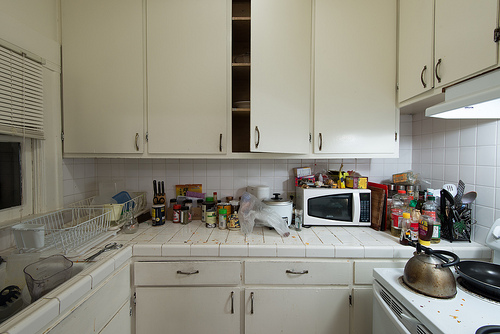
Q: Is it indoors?
A: Yes, it is indoors.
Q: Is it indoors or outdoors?
A: It is indoors.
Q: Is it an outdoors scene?
A: No, it is indoors.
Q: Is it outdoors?
A: No, it is indoors.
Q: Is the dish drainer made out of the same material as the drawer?
A: No, the dish drainer is made of plastic and the drawer is made of wood.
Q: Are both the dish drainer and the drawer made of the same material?
A: No, the dish drainer is made of plastic and the drawer is made of wood.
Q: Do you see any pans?
A: Yes, there is a pan.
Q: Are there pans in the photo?
A: Yes, there is a pan.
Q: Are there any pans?
A: Yes, there is a pan.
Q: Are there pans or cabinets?
A: Yes, there is a pan.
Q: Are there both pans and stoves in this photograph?
A: Yes, there are both a pan and a stove.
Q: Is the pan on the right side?
A: Yes, the pan is on the right of the image.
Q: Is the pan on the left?
A: No, the pan is on the right of the image.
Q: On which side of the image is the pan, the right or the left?
A: The pan is on the right of the image.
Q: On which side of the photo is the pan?
A: The pan is on the right of the image.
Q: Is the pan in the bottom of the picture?
A: Yes, the pan is in the bottom of the image.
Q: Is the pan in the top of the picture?
A: No, the pan is in the bottom of the image.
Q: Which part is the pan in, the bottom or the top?
A: The pan is in the bottom of the image.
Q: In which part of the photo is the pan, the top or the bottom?
A: The pan is in the bottom of the image.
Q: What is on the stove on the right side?
A: The pan is on the stove.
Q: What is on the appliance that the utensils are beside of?
A: The pan is on the stove.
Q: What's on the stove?
A: The pan is on the stove.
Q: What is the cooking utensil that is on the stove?
A: The cooking utensil is a pan.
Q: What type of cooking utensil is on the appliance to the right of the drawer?
A: The cooking utensil is a pan.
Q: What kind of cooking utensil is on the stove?
A: The cooking utensil is a pan.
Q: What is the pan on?
A: The pan is on the stove.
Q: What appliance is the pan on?
A: The pan is on the stove.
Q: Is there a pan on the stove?
A: Yes, there is a pan on the stove.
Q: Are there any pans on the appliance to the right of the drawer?
A: Yes, there is a pan on the stove.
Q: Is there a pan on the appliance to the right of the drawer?
A: Yes, there is a pan on the stove.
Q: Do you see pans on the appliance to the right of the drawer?
A: Yes, there is a pan on the stove.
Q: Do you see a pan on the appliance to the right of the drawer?
A: Yes, there is a pan on the stove.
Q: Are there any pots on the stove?
A: No, there is a pan on the stove.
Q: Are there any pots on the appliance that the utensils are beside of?
A: No, there is a pan on the stove.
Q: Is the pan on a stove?
A: Yes, the pan is on a stove.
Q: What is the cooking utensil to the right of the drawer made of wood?
A: The cooking utensil is a pan.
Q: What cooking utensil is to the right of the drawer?
A: The cooking utensil is a pan.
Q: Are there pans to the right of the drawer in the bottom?
A: Yes, there is a pan to the right of the drawer.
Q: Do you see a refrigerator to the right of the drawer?
A: No, there is a pan to the right of the drawer.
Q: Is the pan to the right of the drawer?
A: Yes, the pan is to the right of the drawer.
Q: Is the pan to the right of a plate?
A: No, the pan is to the right of the drawer.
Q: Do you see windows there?
A: Yes, there is a window.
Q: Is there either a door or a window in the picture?
A: Yes, there is a window.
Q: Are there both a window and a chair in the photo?
A: No, there is a window but no chairs.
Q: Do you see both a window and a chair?
A: No, there is a window but no chairs.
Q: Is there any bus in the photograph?
A: No, there are no buses.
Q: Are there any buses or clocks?
A: No, there are no buses or clocks.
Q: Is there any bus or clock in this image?
A: No, there are no buses or clocks.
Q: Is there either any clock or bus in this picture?
A: No, there are no buses or clocks.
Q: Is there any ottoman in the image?
A: No, there are no ottomen.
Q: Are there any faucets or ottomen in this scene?
A: No, there are no ottomen or faucets.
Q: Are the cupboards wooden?
A: Yes, the cupboards are wooden.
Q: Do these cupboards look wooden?
A: Yes, the cupboards are wooden.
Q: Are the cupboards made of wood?
A: Yes, the cupboards are made of wood.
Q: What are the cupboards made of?
A: The cupboards are made of wood.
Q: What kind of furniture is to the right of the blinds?
A: The pieces of furniture are cupboards.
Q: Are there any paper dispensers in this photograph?
A: No, there are no paper dispensers.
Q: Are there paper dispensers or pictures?
A: No, there are no paper dispensers or pictures.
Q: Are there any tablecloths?
A: No, there are no tablecloths.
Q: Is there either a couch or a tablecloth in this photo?
A: No, there are no tablecloths or couches.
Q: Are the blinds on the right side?
A: No, the blinds are on the left of the image.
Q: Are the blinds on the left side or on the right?
A: The blinds are on the left of the image.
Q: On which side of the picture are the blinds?
A: The blinds are on the left of the image.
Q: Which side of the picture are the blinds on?
A: The blinds are on the left of the image.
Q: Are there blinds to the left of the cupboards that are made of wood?
A: Yes, there are blinds to the left of the cupboards.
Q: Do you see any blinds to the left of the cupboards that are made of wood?
A: Yes, there are blinds to the left of the cupboards.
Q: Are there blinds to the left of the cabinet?
A: Yes, there are blinds to the left of the cabinet.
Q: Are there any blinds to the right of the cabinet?
A: No, the blinds are to the left of the cabinet.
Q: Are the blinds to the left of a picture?
A: No, the blinds are to the left of the cabinet.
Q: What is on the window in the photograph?
A: The blinds are on the window.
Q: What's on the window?
A: The blinds are on the window.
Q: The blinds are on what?
A: The blinds are on the window.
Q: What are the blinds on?
A: The blinds are on the window.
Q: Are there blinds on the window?
A: Yes, there are blinds on the window.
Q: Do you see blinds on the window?
A: Yes, there are blinds on the window.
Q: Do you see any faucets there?
A: No, there are no faucets.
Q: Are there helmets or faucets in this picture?
A: No, there are no faucets or helmets.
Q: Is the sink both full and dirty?
A: Yes, the sink is full and dirty.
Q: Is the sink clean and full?
A: No, the sink is full but dirty.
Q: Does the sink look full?
A: Yes, the sink is full.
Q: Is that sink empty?
A: No, the sink is full.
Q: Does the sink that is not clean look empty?
A: No, the sink is full.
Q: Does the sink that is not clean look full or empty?
A: The sink is full.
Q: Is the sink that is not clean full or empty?
A: The sink is full.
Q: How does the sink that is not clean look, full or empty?
A: The sink is full.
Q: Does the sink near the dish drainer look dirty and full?
A: Yes, the sink is dirty and full.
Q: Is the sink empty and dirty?
A: No, the sink is dirty but full.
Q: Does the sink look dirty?
A: Yes, the sink is dirty.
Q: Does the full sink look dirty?
A: Yes, the sink is dirty.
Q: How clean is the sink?
A: The sink is dirty.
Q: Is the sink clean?
A: No, the sink is dirty.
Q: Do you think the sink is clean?
A: No, the sink is dirty.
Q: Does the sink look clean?
A: No, the sink is dirty.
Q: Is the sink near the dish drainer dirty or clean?
A: The sink is dirty.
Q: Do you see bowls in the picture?
A: No, there are no bowls.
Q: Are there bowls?
A: No, there are no bowls.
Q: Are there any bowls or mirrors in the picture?
A: No, there are no bowls or mirrors.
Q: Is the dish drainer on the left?
A: Yes, the dish drainer is on the left of the image.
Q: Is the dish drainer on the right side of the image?
A: No, the dish drainer is on the left of the image.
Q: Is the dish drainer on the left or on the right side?
A: The dish drainer is on the left of the image.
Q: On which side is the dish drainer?
A: The dish drainer is on the left of the image.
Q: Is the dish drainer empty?
A: Yes, the dish drainer is empty.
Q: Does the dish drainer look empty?
A: Yes, the dish drainer is empty.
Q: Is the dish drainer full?
A: No, the dish drainer is empty.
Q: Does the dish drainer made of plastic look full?
A: No, the dish drainer is empty.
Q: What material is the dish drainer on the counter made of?
A: The dish drainer is made of plastic.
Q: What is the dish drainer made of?
A: The dish drainer is made of plastic.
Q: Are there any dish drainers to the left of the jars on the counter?
A: Yes, there is a dish drainer to the left of the jars.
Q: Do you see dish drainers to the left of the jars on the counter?
A: Yes, there is a dish drainer to the left of the jars.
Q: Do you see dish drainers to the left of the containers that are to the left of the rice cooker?
A: Yes, there is a dish drainer to the left of the jars.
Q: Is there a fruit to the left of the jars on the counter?
A: No, there is a dish drainer to the left of the jars.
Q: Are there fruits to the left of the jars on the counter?
A: No, there is a dish drainer to the left of the jars.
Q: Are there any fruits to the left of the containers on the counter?
A: No, there is a dish drainer to the left of the jars.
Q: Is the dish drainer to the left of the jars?
A: Yes, the dish drainer is to the left of the jars.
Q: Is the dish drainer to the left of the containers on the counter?
A: Yes, the dish drainer is to the left of the jars.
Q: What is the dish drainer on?
A: The dish drainer is on the counter.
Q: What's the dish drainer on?
A: The dish drainer is on the counter.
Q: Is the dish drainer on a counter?
A: Yes, the dish drainer is on a counter.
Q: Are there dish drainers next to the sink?
A: Yes, there is a dish drainer next to the sink.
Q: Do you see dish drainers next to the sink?
A: Yes, there is a dish drainer next to the sink.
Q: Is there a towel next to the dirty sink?
A: No, there is a dish drainer next to the sink.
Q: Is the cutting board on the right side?
A: Yes, the cutting board is on the right of the image.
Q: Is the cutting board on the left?
A: No, the cutting board is on the right of the image.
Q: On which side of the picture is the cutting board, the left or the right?
A: The cutting board is on the right of the image.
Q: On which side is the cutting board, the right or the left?
A: The cutting board is on the right of the image.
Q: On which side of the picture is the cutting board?
A: The cutting board is on the right of the image.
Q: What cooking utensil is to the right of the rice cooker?
A: The cooking utensil is a cutting board.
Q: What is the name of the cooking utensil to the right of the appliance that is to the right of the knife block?
A: The cooking utensil is a cutting board.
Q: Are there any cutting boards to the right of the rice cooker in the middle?
A: Yes, there is a cutting board to the right of the rice cooker.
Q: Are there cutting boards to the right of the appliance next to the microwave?
A: Yes, there is a cutting board to the right of the rice cooker.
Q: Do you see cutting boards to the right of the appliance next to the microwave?
A: Yes, there is a cutting board to the right of the rice cooker.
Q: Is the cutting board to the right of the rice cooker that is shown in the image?
A: Yes, the cutting board is to the right of the rice cooker.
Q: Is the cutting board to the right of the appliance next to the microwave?
A: Yes, the cutting board is to the right of the rice cooker.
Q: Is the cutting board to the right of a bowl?
A: No, the cutting board is to the right of the rice cooker.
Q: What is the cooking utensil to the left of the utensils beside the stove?
A: The cooking utensil is a cutting board.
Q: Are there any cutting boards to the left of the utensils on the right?
A: Yes, there is a cutting board to the left of the utensils.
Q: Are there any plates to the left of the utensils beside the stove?
A: No, there is a cutting board to the left of the utensils.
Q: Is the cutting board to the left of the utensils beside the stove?
A: Yes, the cutting board is to the left of the utensils.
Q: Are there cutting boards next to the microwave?
A: Yes, there is a cutting board next to the microwave.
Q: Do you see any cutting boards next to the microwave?
A: Yes, there is a cutting board next to the microwave.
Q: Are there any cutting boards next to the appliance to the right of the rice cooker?
A: Yes, there is a cutting board next to the microwave.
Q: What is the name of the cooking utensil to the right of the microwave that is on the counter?
A: The cooking utensil is a cutting board.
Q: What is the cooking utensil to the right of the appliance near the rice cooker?
A: The cooking utensil is a cutting board.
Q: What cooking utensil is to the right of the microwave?
A: The cooking utensil is a cutting board.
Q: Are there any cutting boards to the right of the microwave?
A: Yes, there is a cutting board to the right of the microwave.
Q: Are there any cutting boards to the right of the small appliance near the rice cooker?
A: Yes, there is a cutting board to the right of the microwave.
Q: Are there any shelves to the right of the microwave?
A: No, there is a cutting board to the right of the microwave.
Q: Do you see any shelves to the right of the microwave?
A: No, there is a cutting board to the right of the microwave.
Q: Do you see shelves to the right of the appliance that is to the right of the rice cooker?
A: No, there is a cutting board to the right of the microwave.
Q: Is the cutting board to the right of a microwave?
A: Yes, the cutting board is to the right of a microwave.